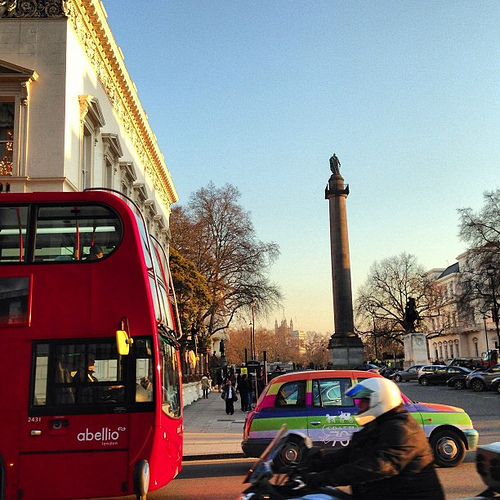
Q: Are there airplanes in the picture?
A: No, there are no airplanes.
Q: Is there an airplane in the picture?
A: No, there are no airplanes.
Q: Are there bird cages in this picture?
A: No, there are no bird cages.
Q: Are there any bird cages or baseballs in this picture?
A: No, there are no bird cages or baseballs.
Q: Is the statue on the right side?
A: Yes, the statue is on the right of the image.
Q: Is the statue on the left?
A: No, the statue is on the right of the image.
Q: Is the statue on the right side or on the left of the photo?
A: The statue is on the right of the image.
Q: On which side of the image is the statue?
A: The statue is on the right of the image.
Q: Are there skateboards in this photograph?
A: No, there are no skateboards.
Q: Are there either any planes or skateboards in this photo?
A: No, there are no skateboards or planes.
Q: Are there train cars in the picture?
A: No, there are no train cars.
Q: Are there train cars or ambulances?
A: No, there are no train cars or ambulances.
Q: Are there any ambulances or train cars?
A: No, there are no train cars or ambulances.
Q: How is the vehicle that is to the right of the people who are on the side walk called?
A: The vehicle is a car.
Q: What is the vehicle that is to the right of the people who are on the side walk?
A: The vehicle is a car.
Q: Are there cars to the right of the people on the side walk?
A: Yes, there is a car to the right of the people.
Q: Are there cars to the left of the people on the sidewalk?
A: No, the car is to the right of the people.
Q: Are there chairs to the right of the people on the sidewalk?
A: No, there is a car to the right of the people.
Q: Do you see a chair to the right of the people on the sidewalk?
A: No, there is a car to the right of the people.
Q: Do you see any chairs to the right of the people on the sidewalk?
A: No, there is a car to the right of the people.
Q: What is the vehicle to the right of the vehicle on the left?
A: The vehicle is a car.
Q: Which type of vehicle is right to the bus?
A: The vehicle is a car.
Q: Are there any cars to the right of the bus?
A: Yes, there is a car to the right of the bus.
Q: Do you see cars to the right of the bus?
A: Yes, there is a car to the right of the bus.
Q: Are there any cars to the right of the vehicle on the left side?
A: Yes, there is a car to the right of the bus.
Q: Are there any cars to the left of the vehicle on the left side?
A: No, the car is to the right of the bus.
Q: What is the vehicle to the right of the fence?
A: The vehicle is a car.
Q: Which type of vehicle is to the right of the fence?
A: The vehicle is a car.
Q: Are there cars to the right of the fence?
A: Yes, there is a car to the right of the fence.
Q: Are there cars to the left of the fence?
A: No, the car is to the right of the fence.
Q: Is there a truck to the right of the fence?
A: No, there is a car to the right of the fence.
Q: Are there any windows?
A: Yes, there are windows.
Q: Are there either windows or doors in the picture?
A: Yes, there are windows.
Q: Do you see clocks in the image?
A: No, there are no clocks.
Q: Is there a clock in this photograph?
A: No, there are no clocks.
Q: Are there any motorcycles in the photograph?
A: Yes, there is a motorcycle.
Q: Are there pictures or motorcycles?
A: Yes, there is a motorcycle.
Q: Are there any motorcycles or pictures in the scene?
A: Yes, there is a motorcycle.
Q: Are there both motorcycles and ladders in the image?
A: No, there is a motorcycle but no ladders.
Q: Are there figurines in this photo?
A: No, there are no figurines.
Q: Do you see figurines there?
A: No, there are no figurines.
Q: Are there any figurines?
A: No, there are no figurines.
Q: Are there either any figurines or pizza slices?
A: No, there are no figurines or pizza slices.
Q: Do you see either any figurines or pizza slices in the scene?
A: No, there are no figurines or pizza slices.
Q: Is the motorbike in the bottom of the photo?
A: Yes, the motorbike is in the bottom of the image.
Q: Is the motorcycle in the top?
A: No, the motorcycle is in the bottom of the image.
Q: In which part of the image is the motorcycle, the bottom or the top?
A: The motorcycle is in the bottom of the image.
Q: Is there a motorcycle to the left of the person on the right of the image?
A: Yes, there is a motorcycle to the left of the person.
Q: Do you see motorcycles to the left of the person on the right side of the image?
A: Yes, there is a motorcycle to the left of the person.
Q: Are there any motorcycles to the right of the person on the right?
A: No, the motorcycle is to the left of the person.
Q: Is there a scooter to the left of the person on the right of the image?
A: No, there is a motorcycle to the left of the person.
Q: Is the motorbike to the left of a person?
A: Yes, the motorbike is to the left of a person.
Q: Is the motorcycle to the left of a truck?
A: No, the motorcycle is to the left of a person.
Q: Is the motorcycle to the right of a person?
A: No, the motorcycle is to the left of a person.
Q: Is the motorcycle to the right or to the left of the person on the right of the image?
A: The motorcycle is to the left of the person.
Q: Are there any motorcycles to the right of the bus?
A: Yes, there is a motorcycle to the right of the bus.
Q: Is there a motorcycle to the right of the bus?
A: Yes, there is a motorcycle to the right of the bus.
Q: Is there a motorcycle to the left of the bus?
A: No, the motorcycle is to the right of the bus.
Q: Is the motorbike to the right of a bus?
A: Yes, the motorbike is to the right of a bus.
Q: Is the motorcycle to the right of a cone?
A: No, the motorcycle is to the right of a bus.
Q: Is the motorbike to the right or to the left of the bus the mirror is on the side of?
A: The motorbike is to the right of the bus.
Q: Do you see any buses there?
A: Yes, there is a bus.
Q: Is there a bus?
A: Yes, there is a bus.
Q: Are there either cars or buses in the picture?
A: Yes, there is a bus.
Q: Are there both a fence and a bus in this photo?
A: Yes, there are both a bus and a fence.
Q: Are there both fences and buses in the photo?
A: Yes, there are both a bus and a fence.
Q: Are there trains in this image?
A: No, there are no trains.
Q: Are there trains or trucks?
A: No, there are no trains or trucks.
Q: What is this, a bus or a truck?
A: This is a bus.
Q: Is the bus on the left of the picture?
A: Yes, the bus is on the left of the image.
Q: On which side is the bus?
A: The bus is on the left of the image.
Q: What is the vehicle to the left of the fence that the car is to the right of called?
A: The vehicle is a bus.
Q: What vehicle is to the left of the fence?
A: The vehicle is a bus.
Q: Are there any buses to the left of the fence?
A: Yes, there is a bus to the left of the fence.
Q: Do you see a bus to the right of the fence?
A: No, the bus is to the left of the fence.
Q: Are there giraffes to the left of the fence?
A: No, there is a bus to the left of the fence.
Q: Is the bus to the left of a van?
A: No, the bus is to the left of the fence.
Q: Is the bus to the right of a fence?
A: No, the bus is to the left of a fence.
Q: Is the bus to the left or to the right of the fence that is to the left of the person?
A: The bus is to the left of the fence.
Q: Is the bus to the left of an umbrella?
A: No, the bus is to the left of the car.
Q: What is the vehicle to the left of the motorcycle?
A: The vehicle is a bus.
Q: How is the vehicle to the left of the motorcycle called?
A: The vehicle is a bus.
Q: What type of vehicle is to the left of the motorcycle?
A: The vehicle is a bus.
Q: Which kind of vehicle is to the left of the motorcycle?
A: The vehicle is a bus.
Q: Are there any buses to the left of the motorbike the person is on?
A: Yes, there is a bus to the left of the motorcycle.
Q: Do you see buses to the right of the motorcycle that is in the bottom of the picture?
A: No, the bus is to the left of the motorbike.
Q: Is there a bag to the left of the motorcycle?
A: No, there is a bus to the left of the motorcycle.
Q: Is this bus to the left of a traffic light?
A: No, the bus is to the left of the motorbike.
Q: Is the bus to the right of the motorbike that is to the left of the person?
A: No, the bus is to the left of the motorbike.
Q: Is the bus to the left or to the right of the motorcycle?
A: The bus is to the left of the motorcycle.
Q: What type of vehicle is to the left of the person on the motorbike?
A: The vehicle is a bus.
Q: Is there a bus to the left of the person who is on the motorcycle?
A: Yes, there is a bus to the left of the person.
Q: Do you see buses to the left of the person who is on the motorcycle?
A: Yes, there is a bus to the left of the person.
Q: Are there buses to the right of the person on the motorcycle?
A: No, the bus is to the left of the person.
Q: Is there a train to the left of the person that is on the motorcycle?
A: No, there is a bus to the left of the person.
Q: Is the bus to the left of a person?
A: Yes, the bus is to the left of a person.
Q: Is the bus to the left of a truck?
A: No, the bus is to the left of a person.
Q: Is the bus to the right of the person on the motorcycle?
A: No, the bus is to the left of the person.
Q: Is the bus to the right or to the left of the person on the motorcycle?
A: The bus is to the left of the person.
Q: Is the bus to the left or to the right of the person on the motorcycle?
A: The bus is to the left of the person.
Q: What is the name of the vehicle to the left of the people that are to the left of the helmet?
A: The vehicle is a bus.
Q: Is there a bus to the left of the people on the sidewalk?
A: Yes, there is a bus to the left of the people.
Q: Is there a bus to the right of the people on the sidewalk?
A: No, the bus is to the left of the people.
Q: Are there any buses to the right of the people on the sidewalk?
A: No, the bus is to the left of the people.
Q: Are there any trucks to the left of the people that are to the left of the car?
A: No, there is a bus to the left of the people.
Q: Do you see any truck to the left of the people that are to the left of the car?
A: No, there is a bus to the left of the people.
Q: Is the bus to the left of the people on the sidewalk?
A: Yes, the bus is to the left of the people.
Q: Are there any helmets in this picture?
A: Yes, there is a helmet.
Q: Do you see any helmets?
A: Yes, there is a helmet.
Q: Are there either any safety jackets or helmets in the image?
A: Yes, there is a helmet.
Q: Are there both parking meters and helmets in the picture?
A: No, there is a helmet but no parking meters.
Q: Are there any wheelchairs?
A: No, there are no wheelchairs.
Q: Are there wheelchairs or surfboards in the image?
A: No, there are no wheelchairs or surfboards.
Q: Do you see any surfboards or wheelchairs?
A: No, there are no wheelchairs or surfboards.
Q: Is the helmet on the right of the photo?
A: Yes, the helmet is on the right of the image.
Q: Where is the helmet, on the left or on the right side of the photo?
A: The helmet is on the right of the image.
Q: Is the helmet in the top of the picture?
A: No, the helmet is in the bottom of the image.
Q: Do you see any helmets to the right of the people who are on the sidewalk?
A: Yes, there is a helmet to the right of the people.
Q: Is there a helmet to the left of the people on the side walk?
A: No, the helmet is to the right of the people.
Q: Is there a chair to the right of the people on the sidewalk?
A: No, there is a helmet to the right of the people.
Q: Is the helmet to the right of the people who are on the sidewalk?
A: Yes, the helmet is to the right of the people.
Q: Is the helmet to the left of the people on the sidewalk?
A: No, the helmet is to the right of the people.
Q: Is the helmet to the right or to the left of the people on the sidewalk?
A: The helmet is to the right of the people.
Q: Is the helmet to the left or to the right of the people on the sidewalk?
A: The helmet is to the right of the people.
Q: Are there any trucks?
A: No, there are no trucks.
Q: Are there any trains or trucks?
A: No, there are no trucks or trains.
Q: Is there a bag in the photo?
A: No, there are no bags.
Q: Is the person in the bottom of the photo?
A: Yes, the person is in the bottom of the image.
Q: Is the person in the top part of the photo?
A: No, the person is in the bottom of the image.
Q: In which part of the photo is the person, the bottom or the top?
A: The person is in the bottom of the image.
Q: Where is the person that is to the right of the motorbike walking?
A: The person is walking on the sidewalk.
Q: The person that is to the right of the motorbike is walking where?
A: The person is walking on the sidewalk.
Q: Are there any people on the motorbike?
A: Yes, there is a person on the motorbike.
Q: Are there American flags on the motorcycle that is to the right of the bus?
A: No, there is a person on the motorbike.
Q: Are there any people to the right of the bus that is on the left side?
A: Yes, there is a person to the right of the bus.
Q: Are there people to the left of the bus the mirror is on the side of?
A: No, the person is to the right of the bus.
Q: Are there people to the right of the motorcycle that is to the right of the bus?
A: Yes, there is a person to the right of the motorcycle.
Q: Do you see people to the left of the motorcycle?
A: No, the person is to the right of the motorcycle.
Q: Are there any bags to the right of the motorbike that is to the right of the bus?
A: No, there is a person to the right of the motorcycle.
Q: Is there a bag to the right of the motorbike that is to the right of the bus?
A: No, there is a person to the right of the motorcycle.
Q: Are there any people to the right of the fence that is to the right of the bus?
A: Yes, there is a person to the right of the fence.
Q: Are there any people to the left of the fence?
A: No, the person is to the right of the fence.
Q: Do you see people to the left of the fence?
A: No, the person is to the right of the fence.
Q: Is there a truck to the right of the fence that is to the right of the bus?
A: No, there is a person to the right of the fence.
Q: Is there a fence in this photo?
A: Yes, there is a fence.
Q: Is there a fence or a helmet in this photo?
A: Yes, there is a fence.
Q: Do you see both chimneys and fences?
A: No, there is a fence but no chimneys.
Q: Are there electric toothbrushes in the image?
A: No, there are no electric toothbrushes.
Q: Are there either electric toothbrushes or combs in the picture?
A: No, there are no electric toothbrushes or combs.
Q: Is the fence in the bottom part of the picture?
A: Yes, the fence is in the bottom of the image.